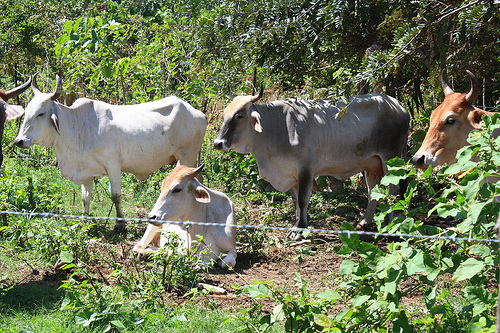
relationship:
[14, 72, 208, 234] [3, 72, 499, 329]
bull on ground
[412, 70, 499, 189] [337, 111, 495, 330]
bull on bush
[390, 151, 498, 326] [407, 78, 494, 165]
bushes on scow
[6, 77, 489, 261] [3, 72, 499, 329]
cattle on ground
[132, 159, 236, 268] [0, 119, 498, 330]
cattle lying in floor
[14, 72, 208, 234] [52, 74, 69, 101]
bull has chunks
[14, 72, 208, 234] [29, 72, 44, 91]
bull has chunks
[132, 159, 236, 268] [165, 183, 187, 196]
cattle has eye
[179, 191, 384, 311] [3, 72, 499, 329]
dirt on ground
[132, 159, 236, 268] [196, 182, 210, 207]
cattle has ear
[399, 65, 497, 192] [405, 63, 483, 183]
bull has head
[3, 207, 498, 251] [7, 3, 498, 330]
wire going though a field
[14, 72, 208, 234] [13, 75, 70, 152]
bull has head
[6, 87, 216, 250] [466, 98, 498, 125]
bull has ear